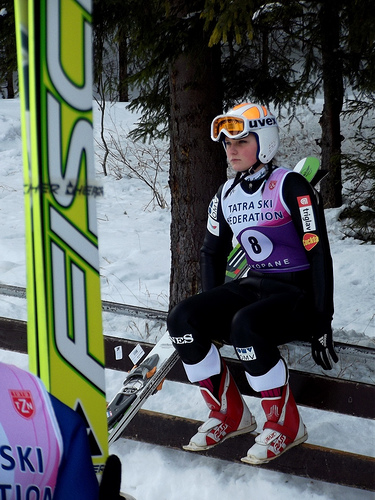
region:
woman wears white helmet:
[216, 90, 285, 173]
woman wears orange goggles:
[216, 104, 244, 134]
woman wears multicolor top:
[221, 173, 328, 288]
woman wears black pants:
[168, 275, 275, 367]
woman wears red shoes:
[194, 372, 280, 447]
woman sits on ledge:
[139, 327, 349, 490]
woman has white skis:
[95, 292, 209, 452]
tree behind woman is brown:
[143, 28, 256, 314]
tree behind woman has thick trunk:
[144, 15, 245, 286]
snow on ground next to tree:
[103, 212, 149, 307]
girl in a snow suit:
[172, 91, 337, 276]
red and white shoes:
[241, 365, 316, 475]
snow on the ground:
[148, 463, 201, 499]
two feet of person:
[179, 384, 309, 475]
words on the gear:
[223, 186, 287, 239]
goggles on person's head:
[197, 109, 266, 143]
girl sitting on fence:
[139, 109, 338, 368]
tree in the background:
[106, 47, 152, 86]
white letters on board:
[52, 69, 93, 362]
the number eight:
[234, 225, 279, 264]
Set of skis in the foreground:
[18, 4, 108, 485]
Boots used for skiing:
[174, 360, 309, 459]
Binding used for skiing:
[122, 350, 155, 385]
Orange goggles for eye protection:
[208, 114, 255, 142]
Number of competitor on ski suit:
[236, 223, 272, 259]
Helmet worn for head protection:
[212, 102, 285, 167]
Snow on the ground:
[123, 215, 165, 285]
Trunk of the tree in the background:
[168, 89, 225, 314]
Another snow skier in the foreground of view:
[4, 344, 122, 499]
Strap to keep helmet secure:
[230, 158, 263, 181]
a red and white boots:
[230, 345, 309, 498]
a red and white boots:
[192, 359, 279, 487]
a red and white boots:
[182, 347, 246, 463]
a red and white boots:
[141, 365, 233, 471]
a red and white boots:
[212, 370, 260, 485]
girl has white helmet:
[224, 104, 278, 177]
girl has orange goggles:
[211, 107, 245, 147]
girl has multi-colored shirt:
[205, 187, 340, 318]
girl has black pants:
[167, 270, 299, 371]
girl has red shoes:
[170, 344, 293, 459]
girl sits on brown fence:
[86, 314, 339, 490]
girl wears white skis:
[85, 272, 207, 444]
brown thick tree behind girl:
[148, 95, 254, 343]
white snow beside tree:
[117, 220, 153, 307]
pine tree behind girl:
[117, 29, 277, 135]